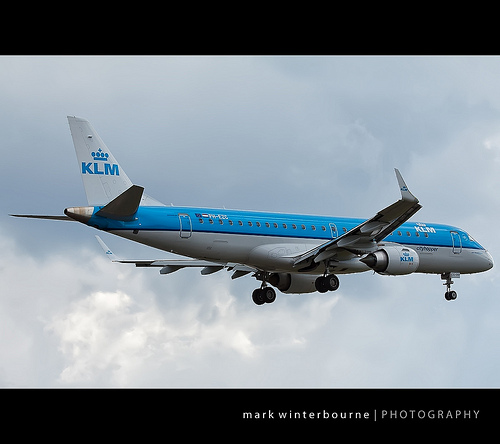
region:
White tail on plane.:
[62, 116, 211, 287]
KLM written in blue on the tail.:
[69, 160, 144, 179]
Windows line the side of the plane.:
[186, 190, 439, 247]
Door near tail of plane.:
[172, 205, 220, 294]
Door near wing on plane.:
[323, 207, 344, 332]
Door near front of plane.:
[444, 224, 483, 289]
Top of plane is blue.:
[162, 206, 444, 255]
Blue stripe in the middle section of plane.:
[176, 217, 331, 252]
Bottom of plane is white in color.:
[195, 222, 345, 297]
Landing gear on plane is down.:
[212, 267, 495, 328]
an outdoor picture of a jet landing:
[0, 54, 498, 386]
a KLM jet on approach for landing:
[8, 115, 493, 305]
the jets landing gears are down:
[316, 259, 338, 292]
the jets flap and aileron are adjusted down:
[274, 199, 411, 271]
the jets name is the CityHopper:
[415, 243, 440, 253]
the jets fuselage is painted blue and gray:
[62, 205, 493, 274]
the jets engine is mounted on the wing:
[351, 241, 419, 275]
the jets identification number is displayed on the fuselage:
[195, 211, 230, 220]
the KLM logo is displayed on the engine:
[398, 249, 415, 264]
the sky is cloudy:
[0, 266, 497, 387]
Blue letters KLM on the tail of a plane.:
[81, 158, 121, 176]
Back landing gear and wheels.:
[248, 272, 277, 307]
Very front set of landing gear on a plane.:
[443, 276, 457, 302]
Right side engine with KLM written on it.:
[358, 242, 420, 277]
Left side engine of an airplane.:
[251, 268, 333, 293]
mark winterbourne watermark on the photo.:
[241, 409, 371, 420]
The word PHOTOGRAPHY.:
[380, 406, 480, 420]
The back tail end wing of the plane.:
[65, 114, 167, 207]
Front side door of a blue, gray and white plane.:
[448, 229, 464, 254]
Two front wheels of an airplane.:
[443, 289, 456, 299]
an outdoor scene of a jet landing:
[0, 54, 498, 386]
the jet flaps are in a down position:
[289, 196, 399, 265]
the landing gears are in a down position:
[441, 272, 458, 299]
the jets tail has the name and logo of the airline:
[65, 113, 167, 205]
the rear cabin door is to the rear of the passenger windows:
[177, 211, 193, 239]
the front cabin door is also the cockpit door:
[449, 230, 463, 254]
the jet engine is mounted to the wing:
[359, 246, 419, 276]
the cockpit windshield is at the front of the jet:
[465, 233, 475, 244]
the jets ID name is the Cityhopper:
[415, 245, 440, 253]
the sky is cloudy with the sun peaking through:
[0, 293, 498, 388]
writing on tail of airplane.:
[82, 149, 112, 174]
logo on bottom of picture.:
[242, 407, 344, 442]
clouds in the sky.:
[112, 315, 198, 349]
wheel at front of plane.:
[438, 285, 470, 301]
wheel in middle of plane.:
[245, 284, 285, 311]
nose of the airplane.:
[480, 232, 491, 272]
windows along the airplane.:
[227, 222, 316, 227]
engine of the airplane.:
[362, 242, 410, 287]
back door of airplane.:
[174, 210, 192, 240]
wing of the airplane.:
[351, 206, 403, 239]